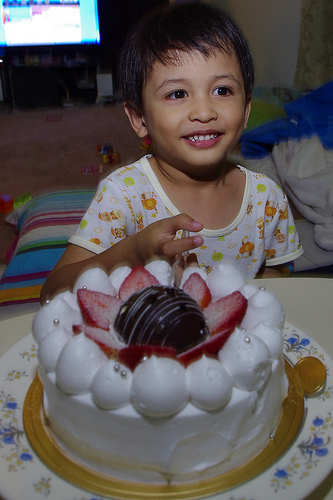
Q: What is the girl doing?
A: Cutting Cake.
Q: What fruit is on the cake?
A: Strawberries.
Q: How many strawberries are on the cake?
A: Seven.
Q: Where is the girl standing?
A: Living room.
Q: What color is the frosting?
A: White.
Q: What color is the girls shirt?
A: White.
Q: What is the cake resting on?
A: Plate.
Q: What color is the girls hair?
A: Black.